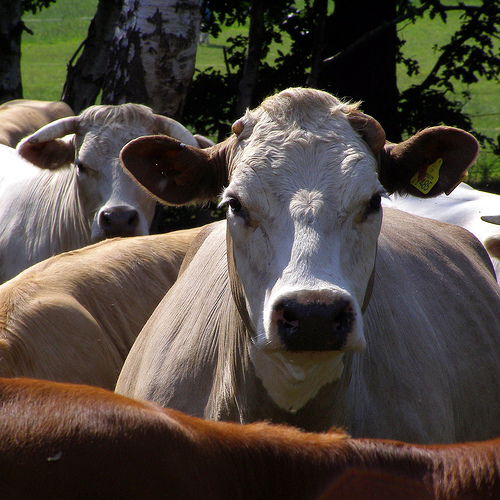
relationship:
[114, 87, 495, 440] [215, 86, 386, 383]
cow has head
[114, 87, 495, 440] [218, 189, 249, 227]
cow has eye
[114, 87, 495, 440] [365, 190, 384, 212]
cow has eye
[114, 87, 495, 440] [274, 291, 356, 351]
cow has nose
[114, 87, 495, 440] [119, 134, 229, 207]
cow has ear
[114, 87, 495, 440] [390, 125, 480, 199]
cow has ear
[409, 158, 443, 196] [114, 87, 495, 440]
tag attached to cow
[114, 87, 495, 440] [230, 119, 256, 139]
cow has horn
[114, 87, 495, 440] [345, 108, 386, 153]
cow has horn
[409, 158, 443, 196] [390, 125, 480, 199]
tag inside ear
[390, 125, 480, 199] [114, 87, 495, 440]
ear part of cow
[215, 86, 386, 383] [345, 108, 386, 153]
head has horn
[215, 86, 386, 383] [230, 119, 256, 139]
head has horn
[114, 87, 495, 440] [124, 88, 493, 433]
cow has fur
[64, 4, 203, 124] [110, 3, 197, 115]
trunk has bark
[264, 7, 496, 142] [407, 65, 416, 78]
tree has leaf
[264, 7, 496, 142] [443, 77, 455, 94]
tree has leaf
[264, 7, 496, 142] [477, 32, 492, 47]
tree has leaf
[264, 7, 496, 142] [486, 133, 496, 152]
tree has leaf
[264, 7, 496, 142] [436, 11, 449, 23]
tree has leaf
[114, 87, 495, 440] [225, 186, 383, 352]
cow has face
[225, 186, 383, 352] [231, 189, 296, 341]
face has shadow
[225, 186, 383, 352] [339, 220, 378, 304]
face has shadow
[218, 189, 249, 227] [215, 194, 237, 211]
eye has lashes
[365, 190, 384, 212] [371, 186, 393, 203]
eye has lashes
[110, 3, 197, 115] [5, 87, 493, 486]
bark behind cows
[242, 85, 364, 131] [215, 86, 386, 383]
hair on top of head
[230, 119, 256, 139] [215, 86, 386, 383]
horn on top of head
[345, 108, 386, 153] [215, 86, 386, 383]
horn on top of head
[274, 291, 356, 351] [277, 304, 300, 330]
nose has nostril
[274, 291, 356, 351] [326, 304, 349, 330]
nose has nostril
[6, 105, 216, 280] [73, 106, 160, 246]
cow has head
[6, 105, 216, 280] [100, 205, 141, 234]
cow has nose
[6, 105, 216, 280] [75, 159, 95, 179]
cow has eye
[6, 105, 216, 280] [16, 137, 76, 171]
cow has ear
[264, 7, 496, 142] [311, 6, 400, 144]
tree has trunk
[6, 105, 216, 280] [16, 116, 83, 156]
cow has horn